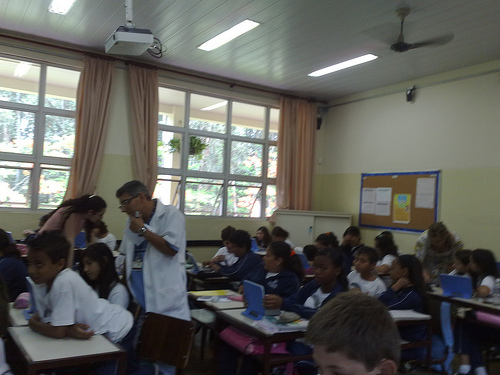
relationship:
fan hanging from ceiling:
[360, 1, 454, 55] [443, 1, 498, 60]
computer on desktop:
[241, 281, 280, 322] [209, 303, 286, 340]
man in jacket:
[103, 166, 195, 330] [118, 197, 190, 323]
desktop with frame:
[211, 313, 296, 358] [220, 313, 262, 338]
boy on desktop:
[28, 226, 159, 373] [1, 310, 118, 363]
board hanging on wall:
[356, 169, 441, 232] [353, 99, 480, 156]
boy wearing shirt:
[28, 226, 134, 346] [55, 275, 115, 328]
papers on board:
[358, 170, 439, 211] [356, 169, 441, 232]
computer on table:
[230, 276, 271, 322] [225, 298, 319, 345]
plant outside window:
[169, 135, 208, 154] [202, 109, 269, 209]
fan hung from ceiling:
[354, 15, 451, 67] [1, 3, 491, 95]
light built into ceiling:
[192, 7, 266, 69] [1, 3, 491, 95]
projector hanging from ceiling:
[96, 24, 173, 67] [5, 0, 498, 105]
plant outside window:
[169, 135, 208, 154] [159, 83, 292, 216]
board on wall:
[356, 169, 441, 232] [309, 81, 499, 259]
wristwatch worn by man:
[134, 222, 151, 245] [115, 180, 191, 322]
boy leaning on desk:
[28, 226, 159, 373] [11, 314, 131, 373]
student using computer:
[289, 240, 362, 324] [247, 285, 302, 324]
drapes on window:
[274, 92, 320, 215] [159, 90, 268, 213]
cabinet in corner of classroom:
[272, 199, 370, 251] [0, 0, 500, 374]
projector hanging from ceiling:
[103, 0, 168, 61] [5, 0, 498, 105]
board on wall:
[351, 169, 446, 233] [322, 76, 499, 256]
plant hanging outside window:
[169, 135, 208, 159] [155, 87, 294, 210]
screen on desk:
[236, 272, 301, 328] [226, 296, 318, 350]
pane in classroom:
[227, 136, 263, 178] [0, 54, 499, 369]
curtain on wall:
[123, 66, 166, 207] [1, 53, 316, 267]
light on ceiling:
[301, 40, 391, 81] [1, 3, 491, 95]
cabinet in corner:
[272, 215, 314, 247] [279, 99, 349, 224]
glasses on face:
[114, 194, 135, 216] [114, 185, 149, 220]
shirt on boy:
[32, 268, 137, 336] [15, 225, 150, 361]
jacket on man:
[112, 197, 198, 327] [109, 178, 203, 372]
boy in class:
[28, 226, 159, 373] [6, 27, 497, 373]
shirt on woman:
[30, 199, 81, 234] [41, 191, 110, 250]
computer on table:
[241, 281, 280, 322] [220, 306, 318, 373]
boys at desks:
[261, 245, 379, 295] [292, 254, 468, 341]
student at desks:
[236, 240, 304, 300] [292, 254, 468, 341]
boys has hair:
[346, 245, 388, 298] [210, 214, 495, 264]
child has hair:
[295, 280, 416, 372] [302, 280, 409, 367]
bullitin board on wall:
[352, 164, 442, 238] [304, 76, 496, 243]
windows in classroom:
[153, 87, 285, 214] [2, 2, 494, 372]